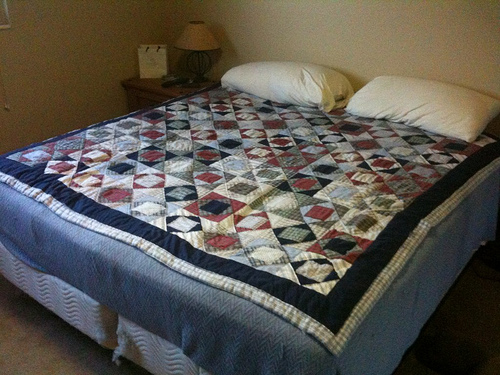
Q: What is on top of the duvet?
A: White pillows.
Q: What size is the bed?
A: Large and wide.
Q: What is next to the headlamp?
A: A notebook.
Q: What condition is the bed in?
A: Well pressed and made.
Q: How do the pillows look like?
A: White and crisp.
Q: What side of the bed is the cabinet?
A: Left side.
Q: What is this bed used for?
A: Sleeping.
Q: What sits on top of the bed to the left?
A: A pillow.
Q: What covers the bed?
A: A comforter.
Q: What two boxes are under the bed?
A: The box springs.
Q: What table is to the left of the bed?
A: The end table.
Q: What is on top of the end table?
A: A lamp.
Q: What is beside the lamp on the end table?
A: A small white bag.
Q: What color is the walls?
A: White.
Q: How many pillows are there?
A: 2.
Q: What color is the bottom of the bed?
A: White.